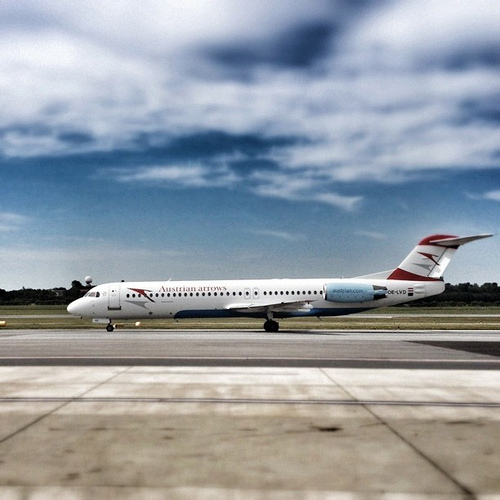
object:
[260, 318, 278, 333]
wheel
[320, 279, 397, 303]
engine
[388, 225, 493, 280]
tail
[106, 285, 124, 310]
door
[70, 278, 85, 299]
trees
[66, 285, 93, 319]
nose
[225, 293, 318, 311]
wing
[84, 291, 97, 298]
windows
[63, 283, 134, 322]
cockpit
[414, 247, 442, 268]
arrows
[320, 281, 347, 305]
propeller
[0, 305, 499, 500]
tarmac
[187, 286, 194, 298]
windows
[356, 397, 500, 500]
cement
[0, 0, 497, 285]
skies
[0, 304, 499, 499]
airport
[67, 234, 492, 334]
airline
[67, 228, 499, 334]
side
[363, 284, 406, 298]
logo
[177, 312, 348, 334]
shadow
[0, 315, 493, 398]
runway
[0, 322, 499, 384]
road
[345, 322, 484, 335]
edge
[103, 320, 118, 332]
wheel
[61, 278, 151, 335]
front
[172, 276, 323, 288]
back